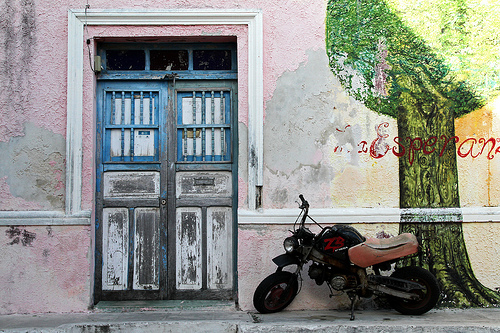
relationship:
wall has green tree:
[237, 2, 498, 306] [323, 0, 498, 309]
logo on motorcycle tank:
[317, 225, 369, 262] [340, 225, 423, 279]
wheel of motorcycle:
[385, 266, 440, 316] [249, 194, 438, 316]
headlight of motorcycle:
[280, 235, 300, 250] [249, 194, 438, 316]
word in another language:
[355, 118, 496, 160] [326, 102, 478, 163]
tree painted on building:
[327, 1, 499, 308] [0, 2, 499, 329]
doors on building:
[94, 34, 236, 309] [4, 3, 442, 332]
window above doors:
[99, 43, 256, 80] [84, 58, 260, 301]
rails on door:
[78, 61, 253, 171] [166, 80, 238, 300]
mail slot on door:
[109, 174, 160, 198] [86, 48, 238, 300]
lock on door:
[159, 194, 168, 208] [92, 76, 239, 301]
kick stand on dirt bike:
[344, 292, 361, 319] [258, 182, 435, 309]